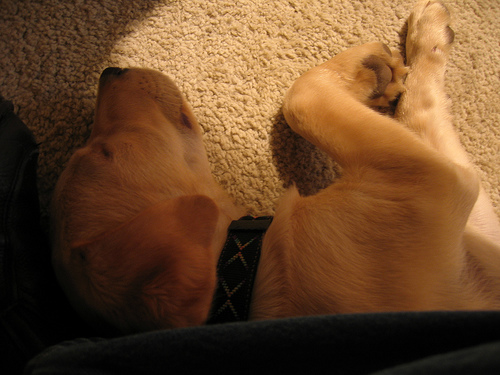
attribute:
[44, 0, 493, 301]
dog — light color, lying, sleeping, brown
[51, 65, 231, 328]
nose — black, dark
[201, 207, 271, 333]
collar — black, thick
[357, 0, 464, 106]
paw — black, tan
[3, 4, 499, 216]
rug — brown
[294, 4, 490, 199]
legs — bend